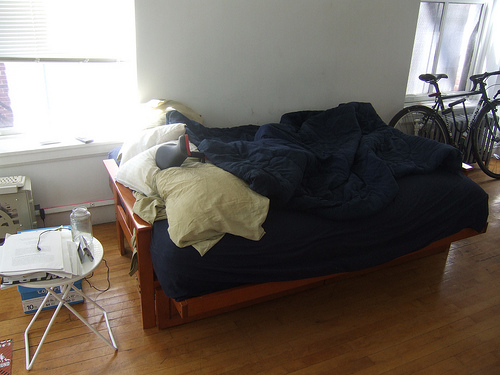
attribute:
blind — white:
[0, 0, 137, 67]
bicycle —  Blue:
[381, 44, 498, 185]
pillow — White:
[73, 72, 287, 275]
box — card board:
[8, 285, 95, 312]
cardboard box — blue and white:
[15, 280, 89, 317]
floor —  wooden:
[0, 159, 498, 374]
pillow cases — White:
[115, 122, 201, 202]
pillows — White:
[111, 104, 261, 240]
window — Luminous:
[2, 3, 137, 150]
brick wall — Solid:
[1, 65, 16, 128]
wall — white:
[132, 7, 426, 118]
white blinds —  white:
[6, 10, 117, 67]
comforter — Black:
[111, 100, 491, 300]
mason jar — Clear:
[65, 202, 97, 256]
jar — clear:
[74, 202, 98, 237]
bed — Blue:
[103, 98, 488, 329]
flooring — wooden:
[359, 332, 398, 365]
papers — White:
[1, 230, 82, 279]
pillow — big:
[152, 160, 264, 253]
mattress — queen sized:
[109, 130, 490, 272]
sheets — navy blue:
[120, 125, 477, 253]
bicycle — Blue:
[388, 70, 498, 181]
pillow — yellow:
[153, 156, 269, 257]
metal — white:
[14, 302, 131, 353]